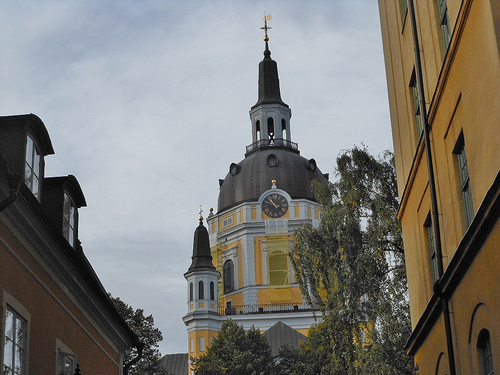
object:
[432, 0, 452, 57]
window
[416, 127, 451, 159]
ground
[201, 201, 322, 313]
wall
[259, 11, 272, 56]
antenna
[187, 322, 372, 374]
wall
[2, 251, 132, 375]
wall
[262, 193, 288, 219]
black clock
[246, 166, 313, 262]
wall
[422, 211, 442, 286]
window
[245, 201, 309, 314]
wall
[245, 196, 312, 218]
top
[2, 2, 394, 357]
clouds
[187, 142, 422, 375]
leaves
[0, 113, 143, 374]
building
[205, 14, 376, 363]
bell tower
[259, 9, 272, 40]
cross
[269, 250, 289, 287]
window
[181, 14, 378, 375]
building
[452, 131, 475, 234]
window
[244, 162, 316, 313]
wall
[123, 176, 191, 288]
clud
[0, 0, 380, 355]
sky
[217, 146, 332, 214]
dome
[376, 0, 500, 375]
building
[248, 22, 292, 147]
top